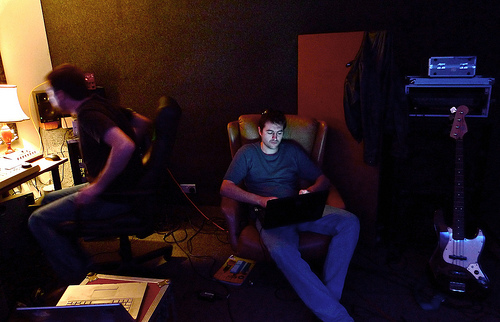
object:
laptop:
[16, 283, 151, 322]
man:
[218, 115, 361, 322]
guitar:
[429, 104, 468, 291]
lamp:
[0, 85, 29, 155]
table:
[0, 146, 62, 196]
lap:
[255, 189, 329, 231]